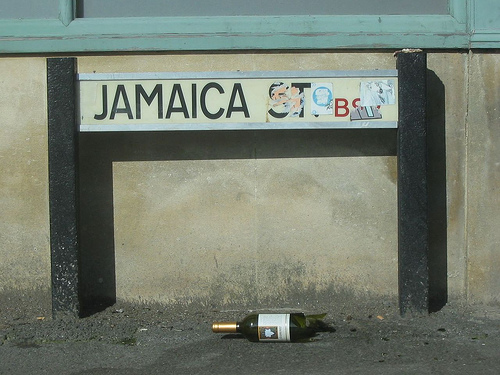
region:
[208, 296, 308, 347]
this is a bottle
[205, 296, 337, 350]
the bottle is broken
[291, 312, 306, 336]
the bottle is green in color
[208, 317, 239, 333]
the top is closed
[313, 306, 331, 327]
the broken pieces are sharp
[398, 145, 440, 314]
this is a pillar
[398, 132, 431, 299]
the pillar is thin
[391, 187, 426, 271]
the pillar is black in color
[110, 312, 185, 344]
the pieces are all over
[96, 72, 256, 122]
it is written jamaica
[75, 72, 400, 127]
a sign for jamaica street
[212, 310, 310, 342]
a broken wine bottle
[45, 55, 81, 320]
a black post for a sign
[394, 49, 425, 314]
a black post for a sign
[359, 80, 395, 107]
worn sticker on a sign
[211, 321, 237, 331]
foil on a wine bottle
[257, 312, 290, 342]
a label on a wine bottle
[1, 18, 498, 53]
a green painted wall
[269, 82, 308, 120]
street scratched off of a sign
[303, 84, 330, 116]
a worn sticker on a sign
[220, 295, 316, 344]
A wine bottle lying on the ground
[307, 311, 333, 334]
A broken shard of glass on the ground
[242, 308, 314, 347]
The wine bottle has a green tint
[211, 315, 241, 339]
The golden cap of the wine bottle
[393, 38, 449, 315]
A thick black post by the wall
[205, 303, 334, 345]
The wine bottle has been broken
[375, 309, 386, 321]
A cigarette butt by the wine bottle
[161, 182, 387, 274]
A plain grey slab wall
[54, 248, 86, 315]
White paint flecks on the black post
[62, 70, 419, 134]
The white sign says "Jamaica St."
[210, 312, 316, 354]
this is a bottle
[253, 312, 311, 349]
the bottle is made of glass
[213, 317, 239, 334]
this is the lid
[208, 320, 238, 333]
the lid is metallic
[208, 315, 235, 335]
the lid is brown in color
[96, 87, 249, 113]
this is a writing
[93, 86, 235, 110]
the writing is in black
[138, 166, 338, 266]
this is the wall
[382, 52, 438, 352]
this is a pole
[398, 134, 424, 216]
the pole is black in color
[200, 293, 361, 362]
a bottle in the floor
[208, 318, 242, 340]
top of the bottle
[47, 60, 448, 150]
street board written in black color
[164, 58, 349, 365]
a bottle under the street board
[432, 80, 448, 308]
shadow of the street board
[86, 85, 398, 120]
yellow color background of the street board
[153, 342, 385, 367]
road near the street board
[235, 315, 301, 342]
a green color bottom of the bottle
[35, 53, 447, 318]
black color stand on the street board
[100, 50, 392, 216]
street name board near the wall